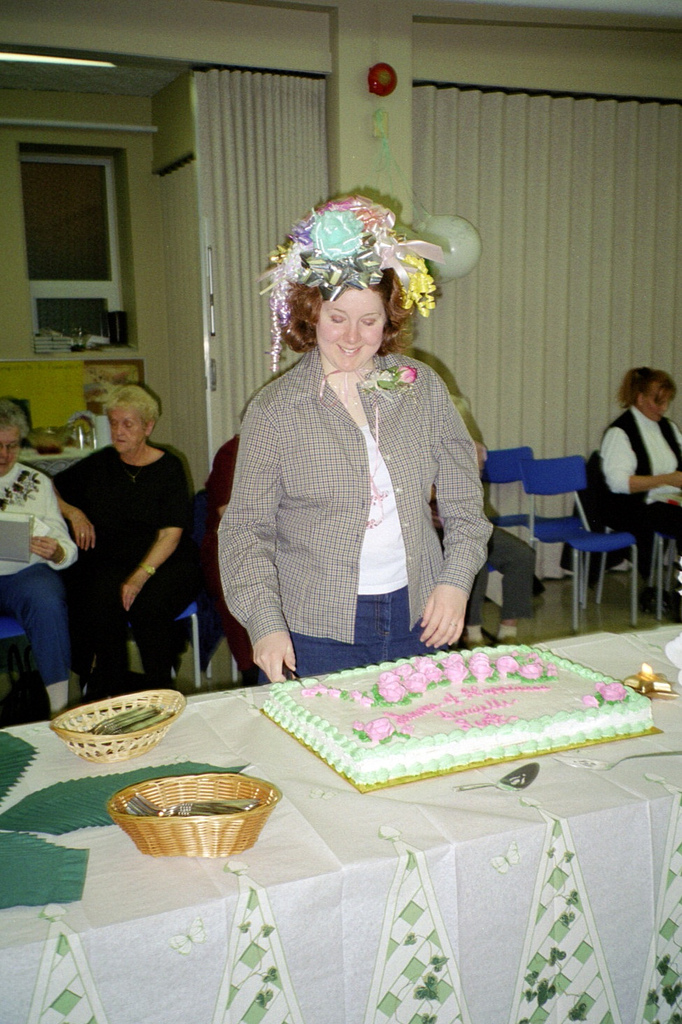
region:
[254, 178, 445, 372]
headpiece made of bows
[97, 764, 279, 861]
round basket on table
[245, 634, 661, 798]
large sheet cake on table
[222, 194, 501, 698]
woman cutting sheet cake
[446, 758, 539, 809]
spatula on table by cake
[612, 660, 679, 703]
candle next to sheet cake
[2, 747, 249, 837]
napkins spread on table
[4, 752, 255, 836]
napkins on table are green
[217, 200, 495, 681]
woman standing at the table cutting the cake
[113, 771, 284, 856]
round wicker basket sitting on the table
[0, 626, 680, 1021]
tablecloth covering the table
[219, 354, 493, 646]
taupe colored jacket the woman is wearing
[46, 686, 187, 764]
oval shape wicker basket sitting on the table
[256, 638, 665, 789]
oblong cake woman is cutting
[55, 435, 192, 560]
black top woman is wearing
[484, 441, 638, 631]
blue chairs sitting on the floor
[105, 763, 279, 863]
basket filled with forks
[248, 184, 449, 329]
birthday party hat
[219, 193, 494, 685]
woman celebrating a birthday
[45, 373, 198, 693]
old lady in black sitting down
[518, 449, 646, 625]
a blue chair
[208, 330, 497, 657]
a flannel shirt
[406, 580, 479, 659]
a womans hand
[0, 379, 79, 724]
an old lady looking at something that she's holding in her hands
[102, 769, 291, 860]
a basket of forks on a table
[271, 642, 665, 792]
a square cake with pink white icing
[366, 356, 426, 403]
a woman with a flower pinned to her shirt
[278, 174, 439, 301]
a woman with several ribbons on her head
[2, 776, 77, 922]
a row of green napkins on a table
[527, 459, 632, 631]
a blue metal chair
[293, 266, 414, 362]
a woman with red hair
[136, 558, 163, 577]
a woman wearing a wrist watch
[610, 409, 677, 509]
a woman wearing a white shirt with black vest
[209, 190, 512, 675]
A woman wearing a hat made of bows that go on presents.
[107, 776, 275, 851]
A brown basket.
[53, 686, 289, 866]
Silverware in baskets on a table.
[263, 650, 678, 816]
A large cake.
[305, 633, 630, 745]
Pink flowers made out of icing on a cake.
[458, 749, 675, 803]
Silver cake spatulas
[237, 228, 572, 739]
A woman cutting a cake.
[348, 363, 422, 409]
A pink flower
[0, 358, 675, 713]
people sitting down in chairs.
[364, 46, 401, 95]
A red fire alarm on the wall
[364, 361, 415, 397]
The flower on the woman jacket.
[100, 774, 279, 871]
The wicker basket on the table.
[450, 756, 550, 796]
The cake spoon.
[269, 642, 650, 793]
The large cake on the table.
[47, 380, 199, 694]
The older woman in all black.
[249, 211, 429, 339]
Ornaments and ribbons on the womans hair.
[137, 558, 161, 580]
The gold watch on the woman wrist.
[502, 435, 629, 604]
The blue unoccupied chair.